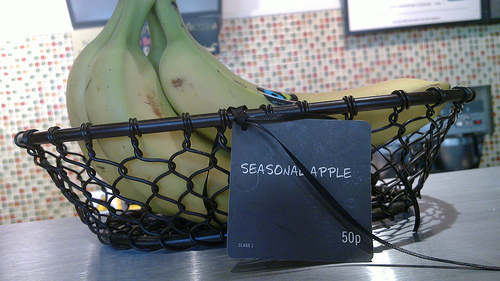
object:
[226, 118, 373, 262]
card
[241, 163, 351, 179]
writing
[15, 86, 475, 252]
basket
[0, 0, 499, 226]
wall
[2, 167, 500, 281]
table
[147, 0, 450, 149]
banana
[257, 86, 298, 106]
label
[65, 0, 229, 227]
banana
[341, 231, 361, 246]
50p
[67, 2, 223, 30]
screen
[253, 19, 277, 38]
tile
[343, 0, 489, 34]
painting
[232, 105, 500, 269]
string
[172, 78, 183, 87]
bruise